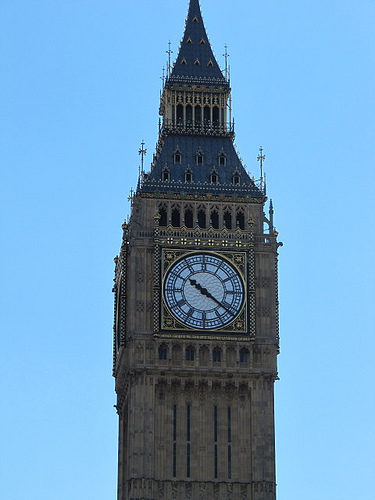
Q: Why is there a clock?
A: It's a clock tower.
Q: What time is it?
A: 10:21.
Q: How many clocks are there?
A: One.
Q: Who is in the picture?
A: No one.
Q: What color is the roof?
A: Blue.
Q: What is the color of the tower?
A: Brown.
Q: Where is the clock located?
A: On the side of the tower.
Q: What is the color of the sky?
A: Blue.